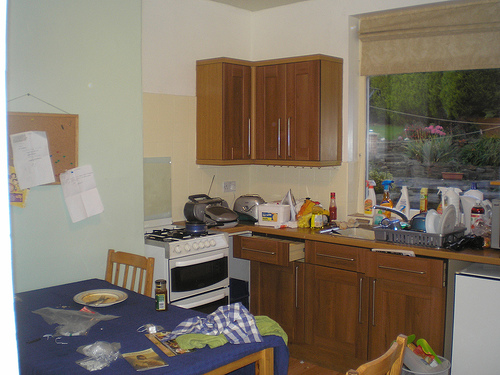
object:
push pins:
[61, 153, 66, 159]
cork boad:
[10, 109, 82, 191]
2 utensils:
[94, 294, 110, 306]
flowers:
[432, 128, 437, 135]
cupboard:
[242, 255, 305, 349]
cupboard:
[209, 216, 299, 269]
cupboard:
[300, 229, 375, 272]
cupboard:
[298, 259, 368, 373]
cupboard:
[367, 272, 448, 372]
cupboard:
[222, 57, 252, 166]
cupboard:
[255, 52, 324, 169]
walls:
[82, 52, 135, 149]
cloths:
[172, 329, 233, 352]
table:
[16, 273, 291, 375]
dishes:
[69, 278, 132, 309]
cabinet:
[189, 51, 252, 168]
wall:
[142, 47, 195, 160]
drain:
[368, 185, 469, 254]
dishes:
[435, 201, 459, 244]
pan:
[171, 219, 220, 242]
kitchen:
[22, 13, 498, 364]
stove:
[147, 219, 239, 321]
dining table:
[17, 275, 288, 374]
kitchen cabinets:
[368, 249, 445, 367]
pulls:
[355, 276, 367, 326]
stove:
[141, 214, 230, 316]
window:
[359, 3, 494, 210]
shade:
[357, 4, 497, 78]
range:
[144, 216, 231, 316]